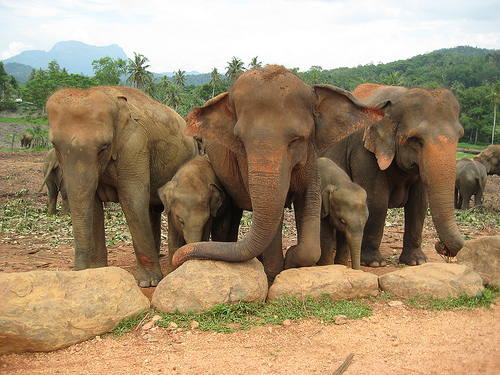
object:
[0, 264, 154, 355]
rocks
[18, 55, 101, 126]
trees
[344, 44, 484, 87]
hill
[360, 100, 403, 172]
ears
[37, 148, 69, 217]
elephant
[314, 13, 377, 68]
clouds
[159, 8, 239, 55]
clouds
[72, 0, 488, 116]
sky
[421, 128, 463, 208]
spot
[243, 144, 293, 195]
spot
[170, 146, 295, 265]
nose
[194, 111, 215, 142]
spots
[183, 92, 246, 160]
ear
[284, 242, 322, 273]
hoof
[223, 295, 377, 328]
grass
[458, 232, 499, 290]
rocks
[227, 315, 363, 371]
soil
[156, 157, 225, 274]
elephant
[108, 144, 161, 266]
leg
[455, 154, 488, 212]
elephant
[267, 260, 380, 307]
rock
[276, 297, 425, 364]
ground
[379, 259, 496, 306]
rock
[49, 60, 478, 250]
elephants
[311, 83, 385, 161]
ear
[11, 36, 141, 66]
mountain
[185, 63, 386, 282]
elephant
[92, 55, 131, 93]
trees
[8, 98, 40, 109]
building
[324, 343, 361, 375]
stick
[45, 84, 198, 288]
elephants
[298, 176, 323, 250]
leg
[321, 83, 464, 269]
elephant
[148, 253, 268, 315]
boulder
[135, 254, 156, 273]
clay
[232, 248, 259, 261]
clay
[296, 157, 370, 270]
elephant